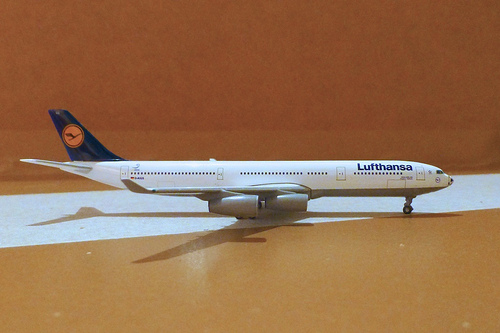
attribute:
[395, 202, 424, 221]
gear — nose, landing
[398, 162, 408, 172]
letter — blue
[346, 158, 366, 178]
letter — blue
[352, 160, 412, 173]
letter — blue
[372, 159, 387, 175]
letter — blue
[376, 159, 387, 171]
letter — blue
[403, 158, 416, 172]
letter — blue